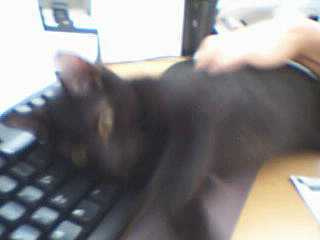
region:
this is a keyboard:
[12, 172, 70, 210]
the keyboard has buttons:
[18, 186, 68, 220]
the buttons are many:
[9, 176, 68, 215]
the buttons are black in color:
[29, 184, 83, 219]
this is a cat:
[36, 66, 298, 159]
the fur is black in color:
[171, 76, 216, 134]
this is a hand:
[202, 7, 318, 56]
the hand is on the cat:
[193, 16, 318, 80]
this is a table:
[259, 194, 276, 213]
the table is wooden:
[250, 218, 277, 231]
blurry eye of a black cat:
[83, 95, 121, 135]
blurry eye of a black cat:
[67, 144, 95, 168]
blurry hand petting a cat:
[195, 26, 269, 88]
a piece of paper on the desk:
[289, 171, 318, 207]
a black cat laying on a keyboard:
[22, 66, 118, 226]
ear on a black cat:
[50, 45, 112, 98]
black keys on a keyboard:
[27, 168, 91, 237]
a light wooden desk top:
[257, 179, 293, 230]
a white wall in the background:
[108, 14, 153, 49]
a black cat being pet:
[9, 20, 306, 238]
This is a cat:
[26, 89, 252, 222]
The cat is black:
[117, 82, 244, 208]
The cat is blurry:
[65, 98, 242, 234]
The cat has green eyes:
[91, 119, 161, 168]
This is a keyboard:
[19, 194, 56, 224]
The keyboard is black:
[45, 200, 72, 221]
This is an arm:
[163, 161, 231, 239]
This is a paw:
[125, 213, 162, 238]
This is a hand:
[236, 45, 294, 60]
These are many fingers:
[181, 59, 216, 100]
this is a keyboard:
[14, 175, 88, 234]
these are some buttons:
[14, 176, 70, 228]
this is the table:
[251, 202, 278, 222]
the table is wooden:
[252, 207, 290, 238]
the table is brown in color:
[250, 202, 277, 225]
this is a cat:
[14, 50, 318, 226]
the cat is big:
[41, 84, 279, 162]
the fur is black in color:
[189, 88, 241, 121]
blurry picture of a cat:
[18, 12, 302, 193]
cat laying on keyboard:
[12, 75, 295, 228]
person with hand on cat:
[177, 16, 316, 96]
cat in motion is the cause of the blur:
[20, 64, 284, 209]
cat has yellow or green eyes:
[44, 90, 122, 165]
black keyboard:
[1, 68, 139, 235]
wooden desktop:
[205, 140, 314, 233]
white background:
[0, 6, 185, 93]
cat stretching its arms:
[144, 99, 260, 227]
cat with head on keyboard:
[9, 60, 152, 174]